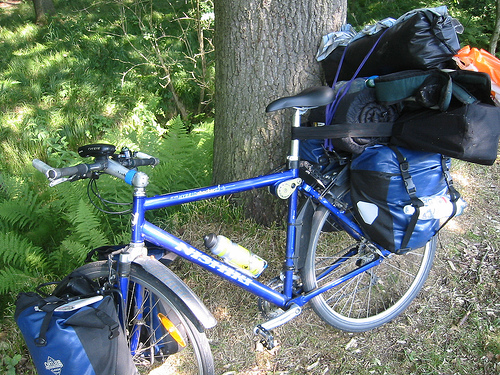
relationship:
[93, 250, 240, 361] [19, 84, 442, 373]
fender on bicycle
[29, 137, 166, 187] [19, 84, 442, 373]
handlebars of bicycle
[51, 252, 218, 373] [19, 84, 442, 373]
wheel of bicycle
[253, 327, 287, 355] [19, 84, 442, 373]
pedal of bicycle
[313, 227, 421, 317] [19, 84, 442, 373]
spokes of bicycle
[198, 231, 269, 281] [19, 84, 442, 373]
water bottle of bicycle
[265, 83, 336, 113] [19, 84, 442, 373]
seat of bicycle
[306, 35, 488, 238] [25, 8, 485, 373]
bags attached to bicycle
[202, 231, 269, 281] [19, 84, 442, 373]
water bottle on bicycle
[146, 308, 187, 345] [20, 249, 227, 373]
reflector on tire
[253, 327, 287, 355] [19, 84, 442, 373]
pedal on bicycle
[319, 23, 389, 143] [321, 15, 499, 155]
blue cord holds items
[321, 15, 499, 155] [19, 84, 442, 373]
items on bicycle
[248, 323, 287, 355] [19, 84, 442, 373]
pedal on bicycle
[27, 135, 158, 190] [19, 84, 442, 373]
handlebars on bicycle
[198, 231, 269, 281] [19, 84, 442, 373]
water bottle connected to bicycle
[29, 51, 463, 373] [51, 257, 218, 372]
bicycle has wheel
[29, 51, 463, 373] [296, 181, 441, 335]
bicycle has rear wheel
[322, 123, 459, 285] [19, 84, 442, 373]
bag connected to bicycle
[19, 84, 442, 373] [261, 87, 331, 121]
bicycle has seat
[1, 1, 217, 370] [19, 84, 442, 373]
grass near bicycle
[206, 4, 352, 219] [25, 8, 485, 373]
tree near bicycle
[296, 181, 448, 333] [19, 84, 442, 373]
rear wheel of bicycle